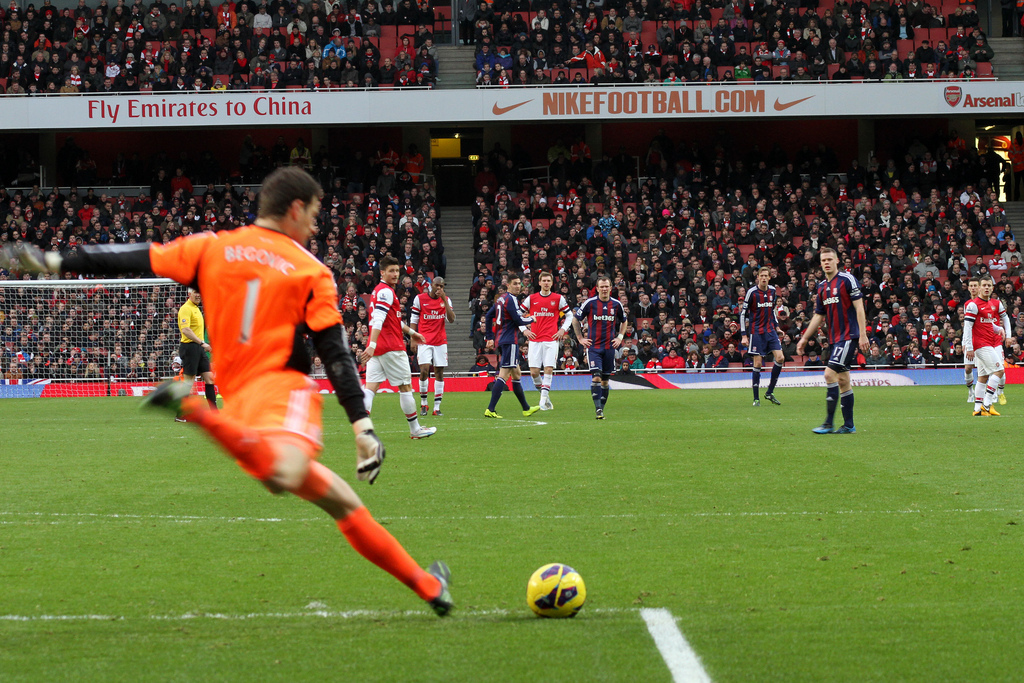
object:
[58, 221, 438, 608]
uniform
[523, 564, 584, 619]
ball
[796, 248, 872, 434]
player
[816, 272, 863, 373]
uniform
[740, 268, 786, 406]
player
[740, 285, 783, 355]
uniform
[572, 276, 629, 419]
player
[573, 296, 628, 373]
uniform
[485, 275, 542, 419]
player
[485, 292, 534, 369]
uniform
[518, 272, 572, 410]
player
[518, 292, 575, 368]
uniform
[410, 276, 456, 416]
player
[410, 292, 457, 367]
uniform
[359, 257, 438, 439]
player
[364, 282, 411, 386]
uniform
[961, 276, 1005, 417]
player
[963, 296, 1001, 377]
uniform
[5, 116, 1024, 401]
stand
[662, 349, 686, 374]
spectator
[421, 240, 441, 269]
spectator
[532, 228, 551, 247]
spectator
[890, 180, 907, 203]
spectator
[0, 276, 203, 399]
net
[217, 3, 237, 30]
spectator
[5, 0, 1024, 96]
stand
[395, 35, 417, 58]
spectator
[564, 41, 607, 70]
spectator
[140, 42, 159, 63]
spectator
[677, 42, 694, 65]
spectator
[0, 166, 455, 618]
man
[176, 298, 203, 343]
shirt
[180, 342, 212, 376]
pants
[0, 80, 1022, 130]
advertisement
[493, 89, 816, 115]
nike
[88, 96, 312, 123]
emirate airlines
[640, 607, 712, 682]
line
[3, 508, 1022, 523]
line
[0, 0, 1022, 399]
stadium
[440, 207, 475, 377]
stairwell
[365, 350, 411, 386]
shorts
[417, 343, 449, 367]
shorts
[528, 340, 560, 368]
shorts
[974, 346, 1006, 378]
shorts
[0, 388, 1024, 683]
field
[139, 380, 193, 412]
cleats